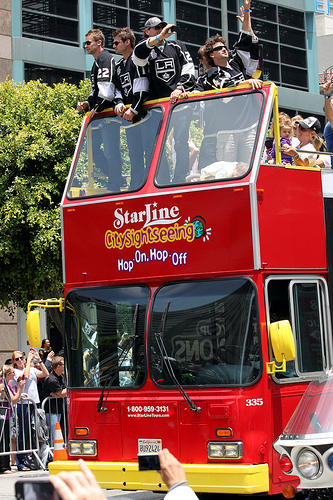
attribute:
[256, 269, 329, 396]
window — side door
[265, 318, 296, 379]
mirror — yellow, side view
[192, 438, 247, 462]
headlight — left front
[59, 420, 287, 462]
headlight — right front